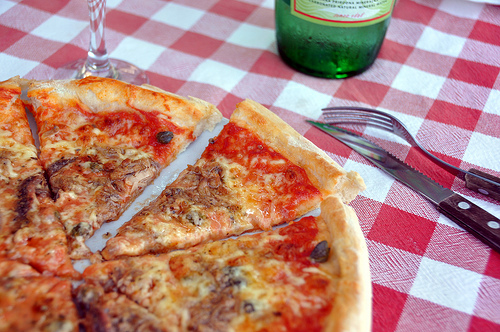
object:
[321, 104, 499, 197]
fork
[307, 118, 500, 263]
knife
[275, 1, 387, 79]
glass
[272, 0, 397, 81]
bottle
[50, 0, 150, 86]
glass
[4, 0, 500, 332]
table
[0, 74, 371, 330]
pizza